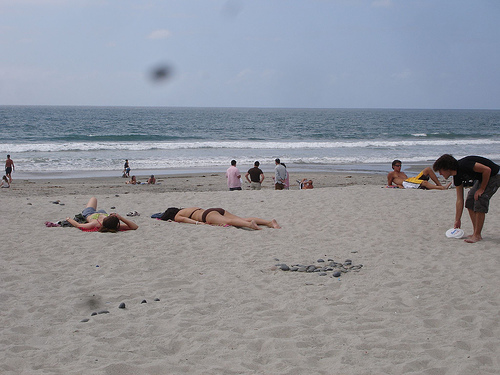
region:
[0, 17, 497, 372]
people at the beach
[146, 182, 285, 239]
lady laying on the sand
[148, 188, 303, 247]
lady wearing a bikini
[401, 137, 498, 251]
guy playing picking up a white frisbee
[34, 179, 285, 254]
two people laying on the sand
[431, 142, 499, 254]
guy wearing a black shirt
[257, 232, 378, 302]
rocks on the sand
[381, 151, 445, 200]
guy with yellow and white shorts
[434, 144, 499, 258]
guy wearing shorts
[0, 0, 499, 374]
blues skies at the beach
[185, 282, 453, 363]
The sand is beige and soft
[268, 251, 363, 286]
The are rocks in a pile on the beach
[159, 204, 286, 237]
A woman is sun bathing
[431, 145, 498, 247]
A man is picking up a Frisbee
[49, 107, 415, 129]
The ocean water is calm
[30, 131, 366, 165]
The waves are washing up on the beach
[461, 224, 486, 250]
The feet of the man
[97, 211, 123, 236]
The head of a woman laying on the beach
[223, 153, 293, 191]
A group of men hanging on the beach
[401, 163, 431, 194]
The man has on yellow, black and white shorts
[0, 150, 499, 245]
people relaxing at the beach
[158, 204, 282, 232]
woman lying down on her belly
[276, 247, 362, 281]
footprints on the sand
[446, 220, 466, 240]
man picking up a white frisbee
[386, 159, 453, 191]
man laying down on his elbows on the sand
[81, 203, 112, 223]
a blue jeans short and a green bikini top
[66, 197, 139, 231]
woman laying down on her back on the sand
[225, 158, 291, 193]
people standing on the beach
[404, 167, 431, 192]
man wearing white and yellow Bermuda shorts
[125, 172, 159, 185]
two people laying down on the sand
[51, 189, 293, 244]
people laying on the bench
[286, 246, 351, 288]
a small pile of rocks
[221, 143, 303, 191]
a group of people watching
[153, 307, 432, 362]
foot prints in the sand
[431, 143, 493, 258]
a young man picking up a frisbee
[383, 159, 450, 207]
A man lying on the bench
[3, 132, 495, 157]
waves in the oceans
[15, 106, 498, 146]
a blue ocean in the back ground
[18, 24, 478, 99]
a clear blue sky above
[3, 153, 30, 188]
a man going into the water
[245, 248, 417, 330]
lumpy sand with stones on it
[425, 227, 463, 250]
white Frisbee on the sand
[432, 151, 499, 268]
man bending over to pick up a white Frisbee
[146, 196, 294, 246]
woman laying on her stomach tanning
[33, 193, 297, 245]
woman laying out tanning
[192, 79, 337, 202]
people standing on the beach staring out at the water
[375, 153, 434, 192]
man without a shirt lounging on the beach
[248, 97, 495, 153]
breaking waves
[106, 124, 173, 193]
people on the beach near the water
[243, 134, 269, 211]
man in a black shirt on the beach